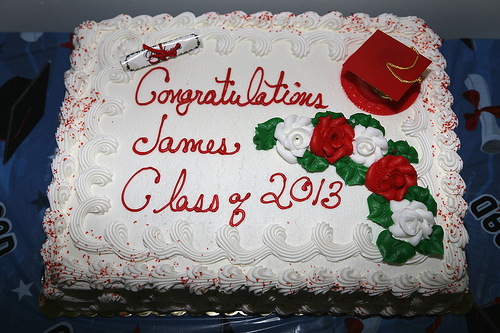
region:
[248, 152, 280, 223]
part of a number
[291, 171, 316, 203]
part of a number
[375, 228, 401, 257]
part of a leaff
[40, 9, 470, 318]
A red and white cake.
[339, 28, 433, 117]
A hat on a cake.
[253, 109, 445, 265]
Flowers on a cake.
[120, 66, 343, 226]
Words on a cake.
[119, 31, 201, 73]
Decoration on a cake.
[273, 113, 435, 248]
Roses on a cake.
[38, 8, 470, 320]
A frosted white cake.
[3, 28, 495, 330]
A blue table cloth.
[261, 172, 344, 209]
Date on a cake.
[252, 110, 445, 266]
Green leaves on a cake.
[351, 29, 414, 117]
the cap is red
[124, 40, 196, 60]
the deploma is white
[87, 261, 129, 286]
the sprinkles are red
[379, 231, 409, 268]
the leaf is green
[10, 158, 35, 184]
the tablecloth is blue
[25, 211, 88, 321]
the cake is sitting on the cloth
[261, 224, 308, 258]
thr frosting is decorative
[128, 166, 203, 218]
the words are red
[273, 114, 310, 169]
the flower is white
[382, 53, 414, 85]
the tassill is gold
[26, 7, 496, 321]
a graduation cake for James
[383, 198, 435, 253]
a white frosting rose on a cake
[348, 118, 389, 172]
a white frosting rose on a cake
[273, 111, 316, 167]
a white frosting rose on a cake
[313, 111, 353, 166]
a red white frosting rose on a cake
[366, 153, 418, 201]
a red white frosting rose on a cake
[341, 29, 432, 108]
a red graduation cap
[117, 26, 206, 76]
a rolled up diploma on a cake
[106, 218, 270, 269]
the frosting edge of a cake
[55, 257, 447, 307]
the trim on a cake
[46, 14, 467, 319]
the cake sitting on the table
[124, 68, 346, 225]
some writing on the cake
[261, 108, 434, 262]
red and white roses surrounded by green leaves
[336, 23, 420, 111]
a graduation cap in the corner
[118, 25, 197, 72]
a decorative diploma in the other corner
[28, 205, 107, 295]
red sprinkles on the cake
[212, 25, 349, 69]
some white frosting on the cake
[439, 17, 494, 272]
a special tablecloth on the table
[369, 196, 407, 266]
some green leaves by the flower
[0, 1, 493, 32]
the wall next to the table